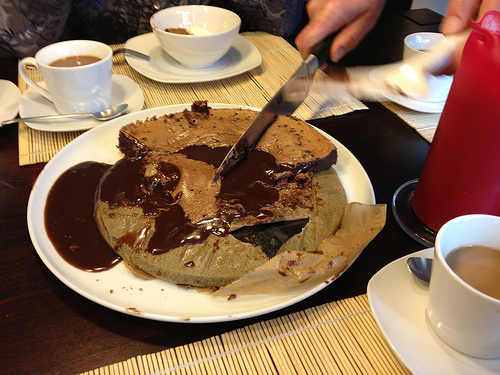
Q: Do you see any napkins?
A: No, there are no napkins.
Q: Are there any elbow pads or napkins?
A: No, there are no napkins or elbow pads.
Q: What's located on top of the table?
A: The placemat is on top of the table.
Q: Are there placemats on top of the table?
A: Yes, there is a placemat on top of the table.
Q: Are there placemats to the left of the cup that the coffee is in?
A: Yes, there is a placemat to the left of the cup.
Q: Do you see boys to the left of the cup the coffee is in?
A: No, there is a placemat to the left of the cup.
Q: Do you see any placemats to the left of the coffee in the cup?
A: Yes, there is a placemat to the left of the coffee.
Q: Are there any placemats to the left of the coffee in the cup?
A: Yes, there is a placemat to the left of the coffee.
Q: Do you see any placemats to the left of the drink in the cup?
A: Yes, there is a placemat to the left of the coffee.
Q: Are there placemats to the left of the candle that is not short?
A: Yes, there is a placemat to the left of the candle.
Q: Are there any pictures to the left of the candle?
A: No, there is a placemat to the left of the candle.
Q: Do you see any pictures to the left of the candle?
A: No, there is a placemat to the left of the candle.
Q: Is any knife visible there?
A: Yes, there is a knife.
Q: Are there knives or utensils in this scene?
A: Yes, there is a knife.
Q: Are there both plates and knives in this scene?
A: Yes, there are both a knife and a plate.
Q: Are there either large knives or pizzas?
A: Yes, there is a large knife.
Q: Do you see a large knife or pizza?
A: Yes, there is a large knife.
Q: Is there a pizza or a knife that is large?
A: Yes, the knife is large.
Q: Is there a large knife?
A: Yes, there is a large knife.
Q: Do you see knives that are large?
A: Yes, there is a knife that is large.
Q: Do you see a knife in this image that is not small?
A: Yes, there is a large knife.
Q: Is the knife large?
A: Yes, the knife is large.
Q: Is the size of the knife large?
A: Yes, the knife is large.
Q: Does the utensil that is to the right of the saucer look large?
A: Yes, the knife is large.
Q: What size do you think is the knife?
A: The knife is large.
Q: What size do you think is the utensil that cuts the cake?
A: The knife is large.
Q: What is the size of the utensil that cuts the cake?
A: The knife is large.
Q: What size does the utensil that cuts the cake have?
A: The knife has large size.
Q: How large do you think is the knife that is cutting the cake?
A: The knife is large.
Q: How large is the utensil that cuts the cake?
A: The knife is large.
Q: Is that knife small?
A: No, the knife is large.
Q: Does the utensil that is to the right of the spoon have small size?
A: No, the knife is large.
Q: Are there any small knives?
A: No, there is a knife but it is large.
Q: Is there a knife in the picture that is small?
A: No, there is a knife but it is large.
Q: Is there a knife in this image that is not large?
A: No, there is a knife but it is large.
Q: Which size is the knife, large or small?
A: The knife is large.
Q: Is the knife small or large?
A: The knife is large.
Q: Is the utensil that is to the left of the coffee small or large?
A: The knife is large.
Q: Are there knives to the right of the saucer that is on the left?
A: Yes, there is a knife to the right of the saucer.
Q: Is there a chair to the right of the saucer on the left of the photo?
A: No, there is a knife to the right of the saucer.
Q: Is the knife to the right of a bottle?
A: No, the knife is to the right of the saucer.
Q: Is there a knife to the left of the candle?
A: Yes, there is a knife to the left of the candle.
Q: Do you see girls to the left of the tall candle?
A: No, there is a knife to the left of the candle.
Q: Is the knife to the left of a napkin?
A: No, the knife is to the left of the candle.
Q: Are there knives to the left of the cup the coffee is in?
A: Yes, there is a knife to the left of the cup.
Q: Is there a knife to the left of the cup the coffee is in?
A: Yes, there is a knife to the left of the cup.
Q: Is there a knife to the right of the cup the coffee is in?
A: No, the knife is to the left of the cup.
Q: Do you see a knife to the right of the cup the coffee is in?
A: No, the knife is to the left of the cup.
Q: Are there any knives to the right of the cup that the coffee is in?
A: No, the knife is to the left of the cup.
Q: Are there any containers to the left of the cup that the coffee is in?
A: No, there is a knife to the left of the cup.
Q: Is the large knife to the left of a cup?
A: Yes, the knife is to the left of a cup.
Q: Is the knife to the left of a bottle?
A: No, the knife is to the left of a cup.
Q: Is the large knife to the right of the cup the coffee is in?
A: No, the knife is to the left of the cup.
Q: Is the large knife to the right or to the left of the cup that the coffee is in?
A: The knife is to the left of the cup.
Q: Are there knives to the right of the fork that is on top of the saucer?
A: Yes, there is a knife to the right of the fork.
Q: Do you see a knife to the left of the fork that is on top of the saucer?
A: No, the knife is to the right of the fork.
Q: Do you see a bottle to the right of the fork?
A: No, there is a knife to the right of the fork.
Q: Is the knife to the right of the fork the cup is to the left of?
A: Yes, the knife is to the right of the fork.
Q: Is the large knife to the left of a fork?
A: No, the knife is to the right of a fork.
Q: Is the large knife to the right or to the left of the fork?
A: The knife is to the right of the fork.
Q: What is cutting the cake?
A: The knife is cutting the cake.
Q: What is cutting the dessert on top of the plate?
A: The knife is cutting the cake.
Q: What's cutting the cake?
A: The knife is cutting the cake.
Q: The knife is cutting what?
A: The knife is cutting the cake.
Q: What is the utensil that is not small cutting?
A: The knife is cutting the cake.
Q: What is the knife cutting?
A: The knife is cutting the cake.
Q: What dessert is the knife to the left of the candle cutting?
A: The knife is cutting the cake.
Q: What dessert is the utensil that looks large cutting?
A: The knife is cutting the cake.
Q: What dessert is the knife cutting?
A: The knife is cutting the cake.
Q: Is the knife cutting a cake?
A: Yes, the knife is cutting a cake.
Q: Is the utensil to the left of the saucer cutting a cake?
A: Yes, the knife is cutting a cake.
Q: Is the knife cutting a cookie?
A: No, the knife is cutting a cake.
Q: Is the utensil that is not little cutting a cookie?
A: No, the knife is cutting a cake.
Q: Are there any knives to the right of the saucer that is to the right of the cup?
A: Yes, there is a knife to the right of the saucer.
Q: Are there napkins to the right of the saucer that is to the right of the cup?
A: No, there is a knife to the right of the saucer.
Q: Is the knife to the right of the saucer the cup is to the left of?
A: Yes, the knife is to the right of the saucer.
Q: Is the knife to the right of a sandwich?
A: No, the knife is to the right of the saucer.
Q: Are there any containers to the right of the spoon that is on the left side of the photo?
A: No, there is a knife to the right of the spoon.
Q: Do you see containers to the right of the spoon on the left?
A: No, there is a knife to the right of the spoon.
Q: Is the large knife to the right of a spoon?
A: Yes, the knife is to the right of a spoon.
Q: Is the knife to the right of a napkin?
A: No, the knife is to the right of a spoon.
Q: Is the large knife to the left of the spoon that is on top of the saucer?
A: No, the knife is to the right of the spoon.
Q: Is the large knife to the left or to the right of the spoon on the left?
A: The knife is to the right of the spoon.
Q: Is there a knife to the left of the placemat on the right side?
A: Yes, there is a knife to the left of the placemat.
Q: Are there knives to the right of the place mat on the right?
A: No, the knife is to the left of the placemat.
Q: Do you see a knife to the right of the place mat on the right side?
A: No, the knife is to the left of the placemat.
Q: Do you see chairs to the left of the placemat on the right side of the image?
A: No, there is a knife to the left of the placemat.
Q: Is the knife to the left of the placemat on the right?
A: Yes, the knife is to the left of the placemat.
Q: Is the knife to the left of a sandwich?
A: No, the knife is to the left of the placemat.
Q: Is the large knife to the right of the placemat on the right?
A: No, the knife is to the left of the placemat.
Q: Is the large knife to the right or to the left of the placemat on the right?
A: The knife is to the left of the placemat.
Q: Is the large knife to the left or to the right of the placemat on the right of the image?
A: The knife is to the left of the placemat.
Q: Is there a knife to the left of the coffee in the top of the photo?
A: Yes, there is a knife to the left of the coffee.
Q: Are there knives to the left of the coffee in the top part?
A: Yes, there is a knife to the left of the coffee.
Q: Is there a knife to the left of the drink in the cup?
A: Yes, there is a knife to the left of the coffee.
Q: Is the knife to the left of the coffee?
A: Yes, the knife is to the left of the coffee.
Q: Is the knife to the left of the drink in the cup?
A: Yes, the knife is to the left of the coffee.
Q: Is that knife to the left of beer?
A: No, the knife is to the left of the coffee.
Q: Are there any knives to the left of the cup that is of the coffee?
A: No, the knife is to the right of the cup.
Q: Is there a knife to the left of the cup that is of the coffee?
A: No, the knife is to the right of the cup.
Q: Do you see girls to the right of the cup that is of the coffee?
A: No, there is a knife to the right of the cup.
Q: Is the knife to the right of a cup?
A: Yes, the knife is to the right of a cup.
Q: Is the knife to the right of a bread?
A: No, the knife is to the right of a cup.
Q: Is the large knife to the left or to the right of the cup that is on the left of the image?
A: The knife is to the right of the cup.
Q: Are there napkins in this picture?
A: No, there are no napkins.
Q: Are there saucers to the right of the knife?
A: Yes, there is a saucer to the right of the knife.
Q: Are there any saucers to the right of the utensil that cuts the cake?
A: Yes, there is a saucer to the right of the knife.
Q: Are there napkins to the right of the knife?
A: No, there is a saucer to the right of the knife.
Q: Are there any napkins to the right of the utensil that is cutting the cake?
A: No, there is a saucer to the right of the knife.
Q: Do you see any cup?
A: Yes, there is a cup.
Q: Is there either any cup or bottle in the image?
A: Yes, there is a cup.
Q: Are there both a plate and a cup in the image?
A: Yes, there are both a cup and a plate.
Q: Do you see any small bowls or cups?
A: Yes, there is a small cup.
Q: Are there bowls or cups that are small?
A: Yes, the cup is small.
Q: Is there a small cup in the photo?
A: Yes, there is a small cup.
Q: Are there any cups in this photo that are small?
A: Yes, there is a cup that is small.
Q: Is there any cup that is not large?
A: Yes, there is a small cup.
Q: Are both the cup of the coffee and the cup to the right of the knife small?
A: Yes, both the cup and the cup are small.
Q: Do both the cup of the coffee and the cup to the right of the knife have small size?
A: Yes, both the cup and the cup are small.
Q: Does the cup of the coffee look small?
A: Yes, the cup is small.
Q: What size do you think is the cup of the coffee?
A: The cup is small.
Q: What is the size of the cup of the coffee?
A: The cup is small.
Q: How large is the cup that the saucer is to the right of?
A: The cup is small.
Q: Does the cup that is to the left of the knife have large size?
A: No, the cup is small.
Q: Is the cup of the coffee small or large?
A: The cup is small.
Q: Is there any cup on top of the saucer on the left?
A: Yes, there is a cup on top of the saucer.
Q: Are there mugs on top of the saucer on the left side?
A: No, there is a cup on top of the saucer.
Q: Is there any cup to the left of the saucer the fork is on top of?
A: Yes, there is a cup to the left of the saucer.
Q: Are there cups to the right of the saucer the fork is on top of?
A: No, the cup is to the left of the saucer.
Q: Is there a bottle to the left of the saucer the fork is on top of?
A: No, there is a cup to the left of the saucer.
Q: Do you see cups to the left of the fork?
A: Yes, there is a cup to the left of the fork.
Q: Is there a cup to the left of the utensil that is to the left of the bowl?
A: Yes, there is a cup to the left of the fork.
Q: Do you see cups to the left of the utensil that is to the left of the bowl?
A: Yes, there is a cup to the left of the fork.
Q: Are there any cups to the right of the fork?
A: No, the cup is to the left of the fork.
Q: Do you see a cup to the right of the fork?
A: No, the cup is to the left of the fork.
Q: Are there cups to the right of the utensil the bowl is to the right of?
A: No, the cup is to the left of the fork.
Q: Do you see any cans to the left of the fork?
A: No, there is a cup to the left of the fork.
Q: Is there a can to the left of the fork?
A: No, there is a cup to the left of the fork.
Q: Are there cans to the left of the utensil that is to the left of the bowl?
A: No, there is a cup to the left of the fork.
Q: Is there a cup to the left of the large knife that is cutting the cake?
A: Yes, there is a cup to the left of the knife.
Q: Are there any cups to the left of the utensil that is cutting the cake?
A: Yes, there is a cup to the left of the knife.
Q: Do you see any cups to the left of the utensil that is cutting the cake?
A: Yes, there is a cup to the left of the knife.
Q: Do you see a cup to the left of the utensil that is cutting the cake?
A: Yes, there is a cup to the left of the knife.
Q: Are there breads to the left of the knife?
A: No, there is a cup to the left of the knife.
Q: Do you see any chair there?
A: No, there are no chairs.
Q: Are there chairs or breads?
A: No, there are no chairs or breads.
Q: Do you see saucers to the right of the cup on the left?
A: Yes, there is a saucer to the right of the cup.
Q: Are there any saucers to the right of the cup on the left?
A: Yes, there is a saucer to the right of the cup.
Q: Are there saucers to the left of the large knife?
A: Yes, there is a saucer to the left of the knife.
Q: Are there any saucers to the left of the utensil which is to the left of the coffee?
A: Yes, there is a saucer to the left of the knife.